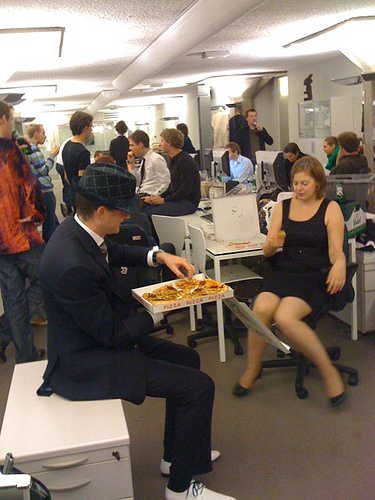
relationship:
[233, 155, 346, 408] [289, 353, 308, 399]
lady sitting down on office chair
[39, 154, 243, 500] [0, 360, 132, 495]
guy siting on cabinet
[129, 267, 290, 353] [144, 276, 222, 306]
box of pizza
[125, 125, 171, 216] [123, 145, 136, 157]
guy eating pizza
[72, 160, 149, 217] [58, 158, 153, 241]
hat on head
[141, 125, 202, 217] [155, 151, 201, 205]
man wearing black shirt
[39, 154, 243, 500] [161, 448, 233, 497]
guy wearing shoes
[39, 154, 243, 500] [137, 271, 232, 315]
guy holding pizza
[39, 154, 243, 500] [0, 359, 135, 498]
guy sitting on trunk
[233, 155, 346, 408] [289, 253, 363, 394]
lady seated in chair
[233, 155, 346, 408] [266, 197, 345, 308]
lady wearing dress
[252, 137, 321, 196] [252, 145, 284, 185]
man seated in front of screen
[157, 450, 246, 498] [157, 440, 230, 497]
shoes on feet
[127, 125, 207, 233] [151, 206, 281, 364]
two men sitting on desk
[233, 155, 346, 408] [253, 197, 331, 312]
lady in dress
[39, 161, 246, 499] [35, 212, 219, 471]
guy in suit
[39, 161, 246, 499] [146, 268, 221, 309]
guy eating pizza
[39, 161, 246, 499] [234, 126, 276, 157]
guy in coat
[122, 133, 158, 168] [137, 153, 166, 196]
guy in dress shirt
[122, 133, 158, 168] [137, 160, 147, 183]
guy in tie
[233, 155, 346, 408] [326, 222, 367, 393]
lady sitting on chair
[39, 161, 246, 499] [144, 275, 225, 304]
guy taking out pizza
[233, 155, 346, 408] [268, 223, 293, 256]
lady holding pizza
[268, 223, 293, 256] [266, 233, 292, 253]
pizza in hand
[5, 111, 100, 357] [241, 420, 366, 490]
people standing in floor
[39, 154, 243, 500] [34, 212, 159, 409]
guy wearing jacket